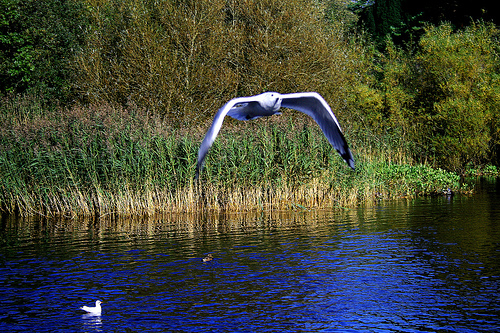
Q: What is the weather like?
A: Sunny.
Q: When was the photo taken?
A: Daytime.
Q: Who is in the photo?
A: Nobody.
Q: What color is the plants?
A: Green.